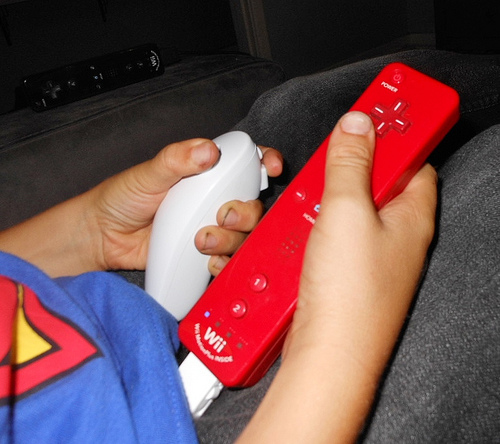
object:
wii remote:
[16, 35, 162, 117]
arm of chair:
[0, 45, 290, 229]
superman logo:
[1, 278, 104, 404]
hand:
[99, 130, 284, 278]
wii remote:
[144, 133, 268, 321]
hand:
[281, 113, 440, 370]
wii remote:
[177, 63, 459, 391]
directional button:
[371, 98, 410, 141]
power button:
[391, 71, 407, 83]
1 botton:
[250, 271, 269, 291]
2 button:
[226, 300, 245, 318]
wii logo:
[204, 326, 227, 353]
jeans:
[196, 40, 500, 444]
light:
[205, 311, 212, 318]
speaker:
[277, 233, 300, 259]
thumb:
[321, 110, 378, 208]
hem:
[0, 247, 195, 444]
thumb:
[124, 139, 218, 191]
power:
[381, 81, 399, 93]